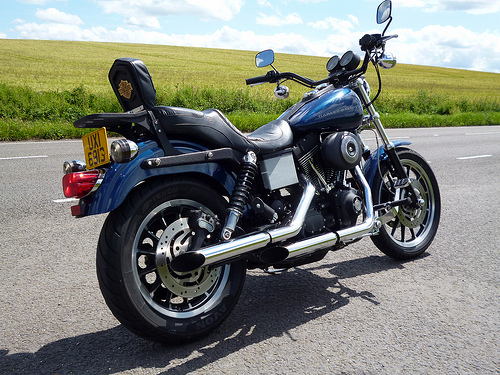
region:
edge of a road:
[388, 337, 399, 361]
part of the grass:
[426, 78, 440, 106]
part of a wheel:
[384, 236, 401, 253]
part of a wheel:
[162, 263, 167, 279]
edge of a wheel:
[416, 200, 430, 238]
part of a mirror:
[380, 19, 386, 39]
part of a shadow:
[271, 303, 278, 313]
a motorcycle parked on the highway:
[53, 1, 441, 349]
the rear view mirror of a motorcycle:
[249, 42, 281, 74]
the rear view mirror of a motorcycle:
[371, 0, 402, 33]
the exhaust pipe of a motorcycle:
[181, 232, 278, 269]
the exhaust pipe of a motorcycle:
[279, 226, 355, 263]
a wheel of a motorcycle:
[364, 145, 442, 261]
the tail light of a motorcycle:
[59, 166, 110, 200]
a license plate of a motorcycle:
[77, 126, 117, 169]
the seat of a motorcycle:
[108, 55, 293, 152]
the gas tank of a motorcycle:
[275, 84, 367, 141]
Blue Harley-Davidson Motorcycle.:
[61, 0, 444, 349]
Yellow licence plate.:
[77, 125, 112, 170]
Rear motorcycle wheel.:
[96, 172, 248, 347]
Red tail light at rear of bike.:
[60, 165, 107, 199]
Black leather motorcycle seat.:
[71, 56, 299, 166]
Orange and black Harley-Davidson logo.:
[116, 77, 133, 100]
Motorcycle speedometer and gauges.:
[326, 50, 362, 72]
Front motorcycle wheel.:
[368, 143, 443, 260]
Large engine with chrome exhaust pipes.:
[157, 125, 378, 275]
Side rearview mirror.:
[253, 49, 275, 69]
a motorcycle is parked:
[79, 1, 461, 317]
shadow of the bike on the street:
[27, 271, 379, 371]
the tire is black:
[84, 167, 261, 340]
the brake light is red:
[45, 159, 101, 201]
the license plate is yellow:
[55, 127, 113, 170]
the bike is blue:
[56, 45, 441, 287]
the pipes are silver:
[150, 182, 409, 292]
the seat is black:
[159, 97, 294, 156]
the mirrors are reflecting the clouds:
[232, 1, 406, 72]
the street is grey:
[334, 262, 481, 357]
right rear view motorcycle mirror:
[361, 1, 408, 45]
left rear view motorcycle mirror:
[245, 46, 286, 71]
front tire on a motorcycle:
[368, 147, 444, 264]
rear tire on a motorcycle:
[91, 171, 253, 349]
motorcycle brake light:
[58, 163, 111, 221]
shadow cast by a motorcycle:
[0, 262, 387, 373]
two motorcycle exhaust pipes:
[167, 186, 380, 276]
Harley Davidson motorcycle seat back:
[102, 49, 159, 109]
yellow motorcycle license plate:
[73, 123, 113, 170]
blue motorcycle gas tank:
[276, 85, 367, 137]